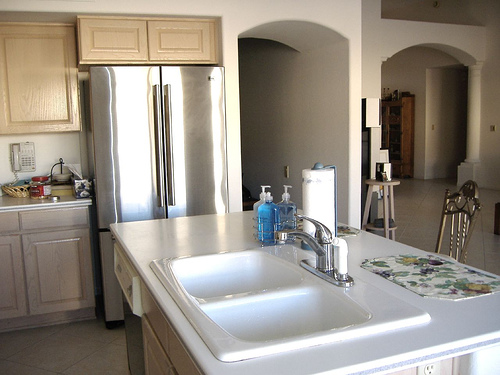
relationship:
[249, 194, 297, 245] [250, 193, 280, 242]
soap in bottle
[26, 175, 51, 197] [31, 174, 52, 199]
nuts in jar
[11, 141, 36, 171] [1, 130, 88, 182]
phone on wall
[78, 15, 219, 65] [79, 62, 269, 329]
cabinet above refrigerator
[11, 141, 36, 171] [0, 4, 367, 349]
phone on wall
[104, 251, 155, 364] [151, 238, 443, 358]
dishwasher under sink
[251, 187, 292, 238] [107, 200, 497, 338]
bottles on counter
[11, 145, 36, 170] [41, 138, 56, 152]
phone on wall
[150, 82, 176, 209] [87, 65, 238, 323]
handles on fridge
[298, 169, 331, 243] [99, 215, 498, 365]
towels on counter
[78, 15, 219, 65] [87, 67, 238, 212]
cabinet over fridge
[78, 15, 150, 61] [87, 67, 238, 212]
cabinet over fridge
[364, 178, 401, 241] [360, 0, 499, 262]
barstool in room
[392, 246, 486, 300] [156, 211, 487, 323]
placemat on counter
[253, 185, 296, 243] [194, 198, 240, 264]
bottles on counter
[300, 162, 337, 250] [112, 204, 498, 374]
dispenser on kitchen counter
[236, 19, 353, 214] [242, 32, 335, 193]
doorway into hallway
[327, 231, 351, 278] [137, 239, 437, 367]
sprayer on sink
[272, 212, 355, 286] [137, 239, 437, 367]
faucet on sink